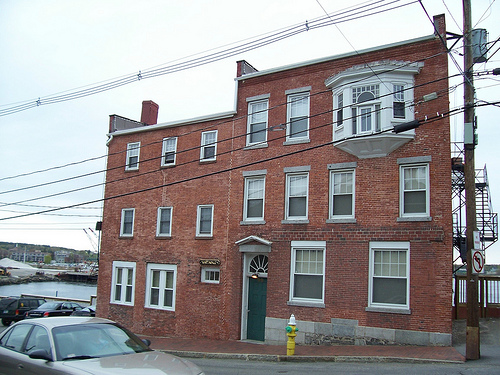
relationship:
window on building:
[247, 93, 271, 146] [93, 7, 460, 348]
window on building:
[285, 92, 314, 140] [93, 7, 460, 348]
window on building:
[242, 180, 265, 219] [93, 7, 460, 348]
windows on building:
[152, 200, 213, 241] [93, 7, 460, 348]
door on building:
[247, 275, 269, 340] [93, 7, 460, 348]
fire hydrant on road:
[287, 313, 297, 354] [0, 319, 500, 375]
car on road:
[3, 303, 209, 371] [1, 319, 500, 369]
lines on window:
[253, 104, 269, 123] [247, 93, 271, 146]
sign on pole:
[470, 249, 486, 272] [404, 1, 461, 361]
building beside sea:
[93, 7, 460, 348] [2, 277, 101, 303]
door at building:
[247, 275, 269, 340] [93, 7, 460, 348]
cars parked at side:
[2, 294, 95, 331] [3, 292, 85, 331]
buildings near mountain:
[9, 237, 50, 250] [12, 244, 92, 260]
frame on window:
[244, 89, 273, 148] [247, 93, 271, 146]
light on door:
[250, 273, 257, 280] [247, 275, 269, 340]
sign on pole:
[470, 249, 486, 272] [460, 0, 481, 361]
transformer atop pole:
[468, 26, 490, 65] [460, 0, 481, 361]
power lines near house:
[4, 0, 496, 224] [89, 145, 460, 352]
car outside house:
[3, 303, 209, 371] [89, 145, 460, 352]